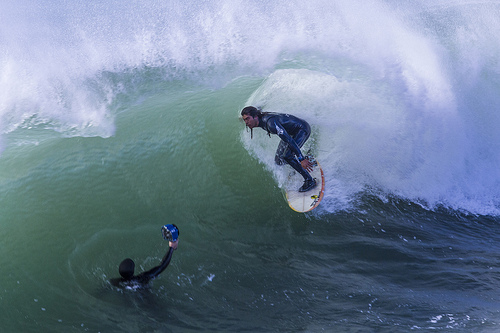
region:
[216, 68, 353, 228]
man surfing the wave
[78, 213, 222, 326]
man in water with camera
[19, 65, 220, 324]
man in water about to get hit by wave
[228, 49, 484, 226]
white splash of crashing wave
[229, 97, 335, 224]
man on prominently white surfboard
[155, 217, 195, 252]
water proof camera in mans right hand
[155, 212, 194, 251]
blue water proof camera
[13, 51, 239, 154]
crest of the wave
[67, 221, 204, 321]
man in black wetsuit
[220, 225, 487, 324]
water getting pulled into wave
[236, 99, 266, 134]
the head of a person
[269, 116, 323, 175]
the arm of a man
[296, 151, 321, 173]
the hand of a man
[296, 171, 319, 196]
the foot of a man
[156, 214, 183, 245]
a blue helmet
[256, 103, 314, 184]
a black wet suit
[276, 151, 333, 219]
a white surfboard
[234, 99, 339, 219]
a man on a surfboard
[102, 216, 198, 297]
a man in the water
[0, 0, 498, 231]
a crashing wave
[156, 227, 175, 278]
the hand of a person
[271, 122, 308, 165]
the hand of a person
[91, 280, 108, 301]
the hand of a person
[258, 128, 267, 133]
the hand of a person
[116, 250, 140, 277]
the head of a person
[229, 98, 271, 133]
the head of a person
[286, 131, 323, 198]
the leg of a person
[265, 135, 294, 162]
the leg of a person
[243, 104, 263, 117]
the hair of a person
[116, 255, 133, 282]
the hair of a person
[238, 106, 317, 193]
Surfer on a surfboard.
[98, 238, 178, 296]
Person with black hair in the water.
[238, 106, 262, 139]
Long dark hair on a man surfing.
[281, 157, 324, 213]
Mostly white colored surfboard in the water.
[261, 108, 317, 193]
Black wetsuit on a surfer in the water.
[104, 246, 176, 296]
Dark black wetsuit on a man in the water.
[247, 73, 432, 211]
Large white wave behind the surfer.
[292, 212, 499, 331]
Dark water under the surfer.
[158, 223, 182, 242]
Large blue and black waterproof camera.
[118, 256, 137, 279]
Black hair of a person in the water.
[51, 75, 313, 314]
people in the water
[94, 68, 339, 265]
the water is the ocean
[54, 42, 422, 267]
picture taken outdoors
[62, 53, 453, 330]
picture taken during the day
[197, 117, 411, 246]
a man on a surf board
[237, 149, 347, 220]
the surfboard is white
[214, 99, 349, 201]
the man is wearing a body suit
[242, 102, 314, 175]
the suit is blue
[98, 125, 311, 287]
the water is green and blue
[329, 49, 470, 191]
the crashing of the waves is white in color